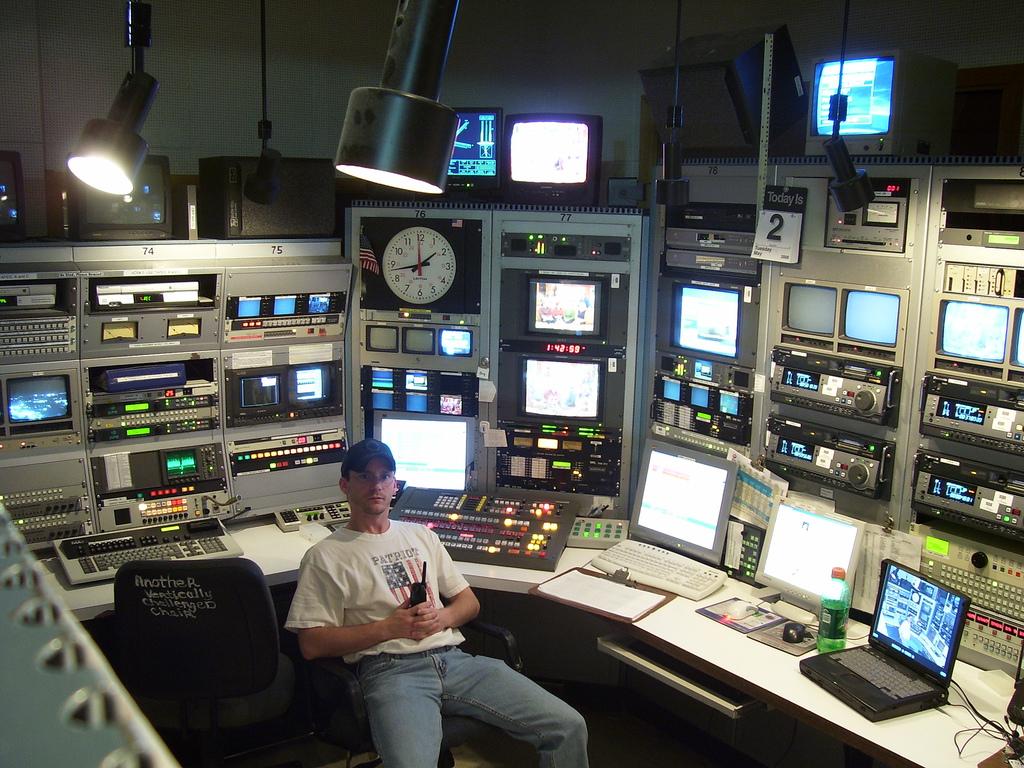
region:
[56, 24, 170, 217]
A light fixture black in color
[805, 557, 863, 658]
A bottle of moutain dew on the desk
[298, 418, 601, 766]
A man sitting comfortably in a office chair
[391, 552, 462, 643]
Hands holding a walkie talkie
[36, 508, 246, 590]
A large type of keyboard on desk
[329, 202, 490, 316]
A clock showing about 1:43 p.m.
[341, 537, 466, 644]
A t-shirt with the American flag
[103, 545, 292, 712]
Unknow writting on back of the chair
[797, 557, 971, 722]
an open laptop computer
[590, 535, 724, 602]
a white computer keyboard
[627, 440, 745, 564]
a built-in computer monitor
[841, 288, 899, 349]
a built-in computer monitor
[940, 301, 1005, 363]
a built-in computer monitor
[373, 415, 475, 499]
a built-in computer monitor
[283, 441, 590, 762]
a man leaning back in chair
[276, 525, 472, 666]
a white shirt with printed American flag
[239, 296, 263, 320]
monitor in front of person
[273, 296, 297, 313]
monitor in front of person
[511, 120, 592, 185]
monitor in front of person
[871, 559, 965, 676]
monitor in front of person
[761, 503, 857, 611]
monitor in front of person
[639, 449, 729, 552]
monitor in front of person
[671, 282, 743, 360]
monitor in front of person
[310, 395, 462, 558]
head of the man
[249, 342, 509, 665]
man with a hat on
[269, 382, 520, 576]
man with glasses on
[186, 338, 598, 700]
man looking at the camera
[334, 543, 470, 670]
item in man's hand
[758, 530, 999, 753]
laptop on table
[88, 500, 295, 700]
writing on the chair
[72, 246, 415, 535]
machines behind the man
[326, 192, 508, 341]
clock behind the man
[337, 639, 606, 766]
Man wearing pants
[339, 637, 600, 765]
Man is wearing pants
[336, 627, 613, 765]
Man wearing blue pants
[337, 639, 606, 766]
Man is wearing blue pants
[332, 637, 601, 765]
Man wearing light blue pants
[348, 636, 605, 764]
Man is wearing light blue pants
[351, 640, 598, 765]
Man wearing blue jeans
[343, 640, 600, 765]
Man is wearing blue jeans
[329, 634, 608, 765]
Man is wearing light blue jeans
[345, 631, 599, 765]
Man wearing light blue jeans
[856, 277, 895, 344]
a monitor on the structure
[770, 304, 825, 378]
a monitor on the structure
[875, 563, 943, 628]
a monitor on the structure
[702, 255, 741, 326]
a monitor on the structure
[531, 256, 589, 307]
a monitor on the structure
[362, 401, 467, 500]
a monitor on the structure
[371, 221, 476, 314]
black and white clock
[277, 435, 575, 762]
man sitting in chair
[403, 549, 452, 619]
black radio held by man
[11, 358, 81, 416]
screen on monitor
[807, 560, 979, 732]
screen on monitor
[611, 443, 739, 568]
screen on monitor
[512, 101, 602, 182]
screen on monitor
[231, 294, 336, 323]
small screen on monitors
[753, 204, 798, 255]
black number on hanging white calendar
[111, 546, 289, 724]
back of black colored chair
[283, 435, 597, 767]
man is sitting in front of control board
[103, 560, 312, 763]
chair is against the desk